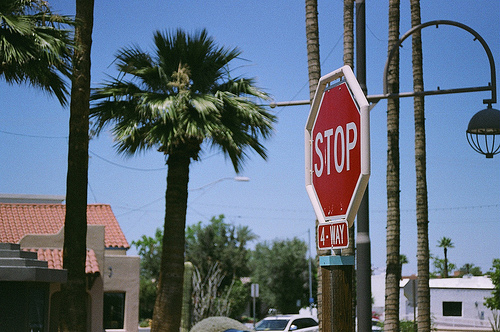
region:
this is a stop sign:
[267, 119, 404, 229]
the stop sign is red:
[285, 114, 380, 239]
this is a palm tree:
[68, 191, 213, 287]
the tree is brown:
[105, 75, 214, 249]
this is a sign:
[236, 279, 271, 321]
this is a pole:
[358, 49, 414, 114]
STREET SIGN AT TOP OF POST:
[295, 54, 383, 325]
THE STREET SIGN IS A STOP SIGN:
[279, 71, 384, 219]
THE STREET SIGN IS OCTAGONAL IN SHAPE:
[298, 66, 372, 226]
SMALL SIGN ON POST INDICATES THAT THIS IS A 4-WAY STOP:
[293, 207, 376, 263]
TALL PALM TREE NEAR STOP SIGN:
[95, 7, 266, 311]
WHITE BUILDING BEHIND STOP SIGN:
[365, 265, 495, 326]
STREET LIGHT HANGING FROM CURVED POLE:
[426, 10, 498, 166]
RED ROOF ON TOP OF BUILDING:
[7, 188, 138, 276]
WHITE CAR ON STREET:
[234, 304, 339, 329]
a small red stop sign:
[299, 76, 376, 211]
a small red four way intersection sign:
[315, 222, 365, 256]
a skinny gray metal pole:
[305, 243, 400, 301]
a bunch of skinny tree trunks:
[286, 2, 427, 83]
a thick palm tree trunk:
[137, 156, 212, 313]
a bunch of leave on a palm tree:
[147, 49, 238, 144]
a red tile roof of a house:
[17, 169, 67, 247]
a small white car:
[230, 303, 298, 330]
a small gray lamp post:
[439, 85, 499, 143]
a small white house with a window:
[427, 261, 497, 331]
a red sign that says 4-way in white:
[315, 220, 350, 249]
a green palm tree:
[87, 28, 275, 329]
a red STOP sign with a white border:
[302, 64, 367, 222]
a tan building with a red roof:
[1, 191, 142, 328]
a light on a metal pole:
[380, 18, 497, 157]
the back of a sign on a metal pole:
[248, 280, 259, 317]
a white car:
[253, 313, 316, 330]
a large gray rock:
[188, 315, 249, 330]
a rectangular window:
[104, 289, 125, 329]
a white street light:
[186, 174, 251, 194]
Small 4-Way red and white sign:
[311, 221, 351, 247]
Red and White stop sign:
[307, 81, 357, 217]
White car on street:
[256, 310, 321, 327]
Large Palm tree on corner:
[87, 22, 277, 327]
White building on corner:
[370, 268, 496, 328]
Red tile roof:
[0, 200, 130, 275]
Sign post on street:
[245, 280, 261, 320]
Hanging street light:
[377, 15, 497, 157]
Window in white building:
[440, 296, 465, 316]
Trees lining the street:
[123, 213, 323, 323]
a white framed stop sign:
[300, 71, 371, 262]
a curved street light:
[384, 24, 499, 330]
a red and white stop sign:
[292, 67, 384, 330]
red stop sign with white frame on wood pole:
[302, 63, 372, 330]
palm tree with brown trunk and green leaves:
[86, 26, 279, 331]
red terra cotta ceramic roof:
[0, 200, 130, 272]